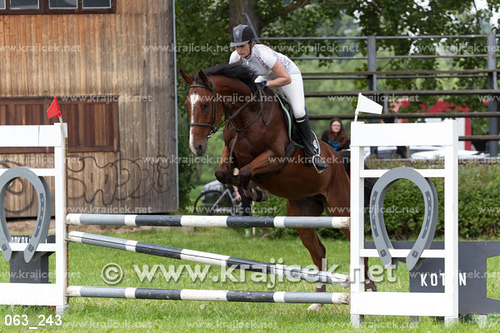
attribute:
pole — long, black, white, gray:
[65, 197, 364, 247]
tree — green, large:
[176, 0, 396, 214]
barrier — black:
[71, 195, 343, 327]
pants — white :
[280, 60, 317, 130]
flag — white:
[350, 90, 385, 121]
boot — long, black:
[283, 124, 368, 194]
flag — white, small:
[353, 91, 384, 121]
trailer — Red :
[395, 108, 478, 163]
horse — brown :
[181, 59, 379, 318]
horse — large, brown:
[174, 53, 381, 295]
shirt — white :
[225, 40, 302, 79]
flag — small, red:
[44, 95, 61, 119]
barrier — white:
[0, 116, 498, 321]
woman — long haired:
[239, 46, 297, 117]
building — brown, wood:
[0, 0, 184, 225]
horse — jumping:
[178, 63, 353, 276]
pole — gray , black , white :
[63, 210, 350, 230]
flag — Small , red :
[44, 94, 71, 126]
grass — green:
[50, 237, 471, 324]